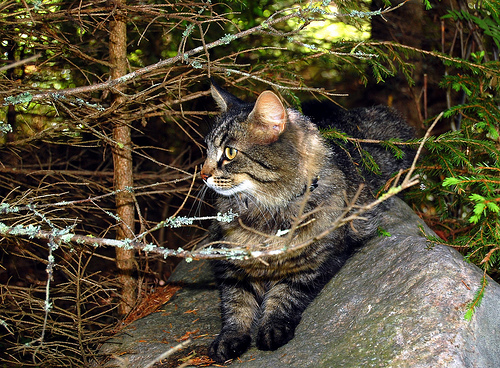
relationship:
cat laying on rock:
[173, 79, 413, 360] [373, 236, 497, 364]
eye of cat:
[222, 144, 242, 164] [173, 79, 413, 360]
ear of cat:
[247, 87, 295, 148] [173, 79, 413, 360]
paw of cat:
[255, 315, 300, 348] [173, 79, 413, 360]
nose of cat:
[197, 165, 214, 185] [173, 79, 413, 360]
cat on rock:
[173, 79, 413, 360] [109, 177, 496, 363]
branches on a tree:
[1, 6, 261, 365] [3, 2, 182, 263]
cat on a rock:
[173, 79, 413, 360] [109, 177, 496, 363]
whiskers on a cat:
[210, 167, 237, 188] [173, 79, 413, 360]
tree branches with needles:
[418, 5, 498, 218] [428, 125, 494, 240]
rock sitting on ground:
[373, 236, 497, 364] [0, 22, 498, 362]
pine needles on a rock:
[460, 276, 495, 321] [373, 236, 497, 364]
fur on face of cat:
[199, 84, 320, 201] [173, 79, 413, 360]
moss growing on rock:
[326, 240, 471, 365] [117, 193, 495, 365]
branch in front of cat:
[6, 102, 447, 276] [186, 84, 422, 334]